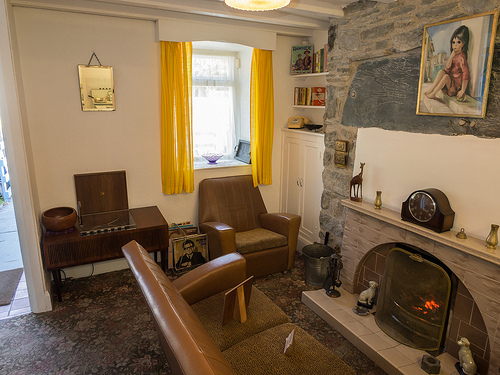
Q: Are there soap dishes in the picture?
A: No, there are no soap dishes.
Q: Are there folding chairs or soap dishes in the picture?
A: No, there are no soap dishes or folding chairs.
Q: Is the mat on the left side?
A: Yes, the mat is on the left of the image.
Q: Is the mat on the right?
A: No, the mat is on the left of the image.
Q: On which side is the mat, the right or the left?
A: The mat is on the left of the image.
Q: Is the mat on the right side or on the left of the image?
A: The mat is on the left of the image.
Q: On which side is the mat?
A: The mat is on the left of the image.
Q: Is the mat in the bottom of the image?
A: Yes, the mat is in the bottom of the image.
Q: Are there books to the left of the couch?
A: No, there is a mat to the left of the couch.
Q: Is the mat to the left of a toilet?
A: No, the mat is to the left of the couch.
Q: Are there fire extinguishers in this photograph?
A: No, there are no fire extinguishers.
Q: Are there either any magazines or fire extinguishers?
A: No, there are no fire extinguishers or magazines.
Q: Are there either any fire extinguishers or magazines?
A: No, there are no fire extinguishers or magazines.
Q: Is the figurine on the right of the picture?
A: Yes, the figurine is on the right of the image.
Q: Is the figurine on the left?
A: No, the figurine is on the right of the image.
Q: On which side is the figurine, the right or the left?
A: The figurine is on the right of the image.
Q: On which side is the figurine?
A: The figurine is on the right of the image.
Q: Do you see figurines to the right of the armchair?
A: Yes, there is a figurine to the right of the armchair.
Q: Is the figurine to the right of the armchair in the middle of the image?
A: Yes, the figurine is to the right of the armchair.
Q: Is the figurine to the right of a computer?
A: No, the figurine is to the right of the armchair.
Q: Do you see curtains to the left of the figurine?
A: Yes, there are curtains to the left of the figurine.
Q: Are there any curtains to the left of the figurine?
A: Yes, there are curtains to the left of the figurine.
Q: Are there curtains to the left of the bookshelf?
A: Yes, there are curtains to the left of the bookshelf.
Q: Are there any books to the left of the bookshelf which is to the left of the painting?
A: No, there are curtains to the left of the bookshelf.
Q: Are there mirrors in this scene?
A: Yes, there is a mirror.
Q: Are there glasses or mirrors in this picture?
A: Yes, there is a mirror.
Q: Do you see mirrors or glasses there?
A: Yes, there is a mirror.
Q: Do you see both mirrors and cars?
A: No, there is a mirror but no cars.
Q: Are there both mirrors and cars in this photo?
A: No, there is a mirror but no cars.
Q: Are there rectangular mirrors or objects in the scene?
A: Yes, there is a rectangular mirror.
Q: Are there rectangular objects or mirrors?
A: Yes, there is a rectangular mirror.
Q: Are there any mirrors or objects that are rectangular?
A: Yes, the mirror is rectangular.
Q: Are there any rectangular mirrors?
A: Yes, there is a rectangular mirror.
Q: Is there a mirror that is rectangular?
A: Yes, there is a mirror that is rectangular.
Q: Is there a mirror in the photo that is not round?
A: Yes, there is a rectangular mirror.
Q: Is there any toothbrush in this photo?
A: No, there are no toothbrushes.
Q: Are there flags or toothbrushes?
A: No, there are no toothbrushes or flags.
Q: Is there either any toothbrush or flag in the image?
A: No, there are no toothbrushes or flags.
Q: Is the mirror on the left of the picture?
A: Yes, the mirror is on the left of the image.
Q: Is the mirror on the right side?
A: No, the mirror is on the left of the image.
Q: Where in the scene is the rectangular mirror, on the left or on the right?
A: The mirror is on the left of the image.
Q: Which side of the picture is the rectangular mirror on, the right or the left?
A: The mirror is on the left of the image.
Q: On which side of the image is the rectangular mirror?
A: The mirror is on the left of the image.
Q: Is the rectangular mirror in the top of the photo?
A: Yes, the mirror is in the top of the image.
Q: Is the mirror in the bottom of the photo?
A: No, the mirror is in the top of the image.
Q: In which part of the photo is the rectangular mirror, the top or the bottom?
A: The mirror is in the top of the image.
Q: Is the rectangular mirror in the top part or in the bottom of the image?
A: The mirror is in the top of the image.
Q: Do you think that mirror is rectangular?
A: Yes, the mirror is rectangular.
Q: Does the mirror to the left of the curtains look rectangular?
A: Yes, the mirror is rectangular.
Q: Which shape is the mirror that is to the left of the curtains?
A: The mirror is rectangular.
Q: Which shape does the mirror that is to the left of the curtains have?
A: The mirror has rectangular shape.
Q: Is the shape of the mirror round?
A: No, the mirror is rectangular.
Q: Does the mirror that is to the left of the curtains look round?
A: No, the mirror is rectangular.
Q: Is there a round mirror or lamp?
A: No, there is a mirror but it is rectangular.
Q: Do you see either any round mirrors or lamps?
A: No, there is a mirror but it is rectangular.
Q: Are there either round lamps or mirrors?
A: No, there is a mirror but it is rectangular.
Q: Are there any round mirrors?
A: No, there is a mirror but it is rectangular.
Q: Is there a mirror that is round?
A: No, there is a mirror but it is rectangular.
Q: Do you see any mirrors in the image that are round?
A: No, there is a mirror but it is rectangular.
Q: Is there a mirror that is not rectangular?
A: No, there is a mirror but it is rectangular.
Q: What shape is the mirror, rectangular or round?
A: The mirror is rectangular.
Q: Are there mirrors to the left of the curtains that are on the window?
A: Yes, there is a mirror to the left of the curtains.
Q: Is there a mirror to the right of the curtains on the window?
A: No, the mirror is to the left of the curtains.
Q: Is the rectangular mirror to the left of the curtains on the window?
A: Yes, the mirror is to the left of the curtains.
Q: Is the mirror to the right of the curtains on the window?
A: No, the mirror is to the left of the curtains.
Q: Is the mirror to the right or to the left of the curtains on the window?
A: The mirror is to the left of the curtains.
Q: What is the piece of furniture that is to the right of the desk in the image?
A: The piece of furniture is an armchair.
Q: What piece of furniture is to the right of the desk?
A: The piece of furniture is an armchair.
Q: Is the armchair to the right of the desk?
A: Yes, the armchair is to the right of the desk.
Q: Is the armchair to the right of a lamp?
A: No, the armchair is to the right of the desk.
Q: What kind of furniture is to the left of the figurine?
A: The piece of furniture is an armchair.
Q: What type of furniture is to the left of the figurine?
A: The piece of furniture is an armchair.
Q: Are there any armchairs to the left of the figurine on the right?
A: Yes, there is an armchair to the left of the figurine.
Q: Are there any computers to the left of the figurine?
A: No, there is an armchair to the left of the figurine.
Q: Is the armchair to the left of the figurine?
A: Yes, the armchair is to the left of the figurine.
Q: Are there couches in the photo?
A: Yes, there is a couch.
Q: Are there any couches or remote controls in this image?
A: Yes, there is a couch.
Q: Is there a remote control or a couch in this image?
A: Yes, there is a couch.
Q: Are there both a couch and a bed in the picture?
A: No, there is a couch but no beds.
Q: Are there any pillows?
A: No, there are no pillows.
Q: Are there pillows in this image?
A: No, there are no pillows.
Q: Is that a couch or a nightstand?
A: That is a couch.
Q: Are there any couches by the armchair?
A: Yes, there is a couch by the armchair.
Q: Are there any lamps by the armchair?
A: No, there is a couch by the armchair.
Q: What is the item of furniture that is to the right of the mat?
A: The piece of furniture is a couch.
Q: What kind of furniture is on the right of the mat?
A: The piece of furniture is a couch.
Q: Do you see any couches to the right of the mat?
A: Yes, there is a couch to the right of the mat.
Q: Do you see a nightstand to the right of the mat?
A: No, there is a couch to the right of the mat.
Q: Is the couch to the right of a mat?
A: Yes, the couch is to the right of a mat.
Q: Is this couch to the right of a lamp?
A: No, the couch is to the right of a mat.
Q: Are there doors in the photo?
A: Yes, there is a door.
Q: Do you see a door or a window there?
A: Yes, there is a door.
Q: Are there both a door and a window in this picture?
A: Yes, there are both a door and a window.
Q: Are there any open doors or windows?
A: Yes, there is an open door.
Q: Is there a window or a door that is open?
A: Yes, the door is open.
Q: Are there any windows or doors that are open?
A: Yes, the door is open.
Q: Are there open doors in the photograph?
A: Yes, there is an open door.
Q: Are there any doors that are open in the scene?
A: Yes, there is an open door.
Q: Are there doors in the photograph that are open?
A: Yes, there is a door that is open.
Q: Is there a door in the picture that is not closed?
A: Yes, there is a open door.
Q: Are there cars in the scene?
A: No, there are no cars.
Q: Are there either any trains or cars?
A: No, there are no cars or trains.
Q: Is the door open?
A: Yes, the door is open.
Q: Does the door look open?
A: Yes, the door is open.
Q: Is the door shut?
A: No, the door is open.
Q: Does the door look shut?
A: No, the door is open.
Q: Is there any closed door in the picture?
A: No, there is a door but it is open.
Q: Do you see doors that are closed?
A: No, there is a door but it is open.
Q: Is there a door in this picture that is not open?
A: No, there is a door but it is open.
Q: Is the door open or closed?
A: The door is open.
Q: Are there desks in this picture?
A: Yes, there is a desk.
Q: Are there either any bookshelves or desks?
A: Yes, there is a desk.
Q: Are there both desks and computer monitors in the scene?
A: No, there is a desk but no computer monitors.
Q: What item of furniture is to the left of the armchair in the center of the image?
A: The piece of furniture is a desk.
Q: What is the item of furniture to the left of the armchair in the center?
A: The piece of furniture is a desk.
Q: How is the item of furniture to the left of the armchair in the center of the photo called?
A: The piece of furniture is a desk.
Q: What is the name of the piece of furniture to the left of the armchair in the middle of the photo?
A: The piece of furniture is a desk.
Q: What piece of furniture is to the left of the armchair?
A: The piece of furniture is a desk.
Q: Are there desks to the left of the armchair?
A: Yes, there is a desk to the left of the armchair.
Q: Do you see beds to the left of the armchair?
A: No, there is a desk to the left of the armchair.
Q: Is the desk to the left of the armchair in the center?
A: Yes, the desk is to the left of the armchair.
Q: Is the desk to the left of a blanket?
A: No, the desk is to the left of the armchair.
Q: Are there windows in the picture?
A: Yes, there is a window.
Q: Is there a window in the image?
A: Yes, there is a window.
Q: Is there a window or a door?
A: Yes, there is a window.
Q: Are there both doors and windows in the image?
A: Yes, there are both a window and a door.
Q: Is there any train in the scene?
A: No, there are no trains.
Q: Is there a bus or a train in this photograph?
A: No, there are no trains or buses.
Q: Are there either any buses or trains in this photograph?
A: No, there are no trains or buses.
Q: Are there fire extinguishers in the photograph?
A: No, there are no fire extinguishers.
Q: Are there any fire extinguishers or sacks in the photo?
A: No, there are no fire extinguishers or sacks.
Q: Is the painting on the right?
A: Yes, the painting is on the right of the image.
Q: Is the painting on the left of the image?
A: No, the painting is on the right of the image.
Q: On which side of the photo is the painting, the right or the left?
A: The painting is on the right of the image.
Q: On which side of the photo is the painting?
A: The painting is on the right of the image.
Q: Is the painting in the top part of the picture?
A: Yes, the painting is in the top of the image.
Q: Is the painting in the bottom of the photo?
A: No, the painting is in the top of the image.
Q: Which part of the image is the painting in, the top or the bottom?
A: The painting is in the top of the image.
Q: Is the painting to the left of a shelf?
A: No, the painting is to the right of a shelf.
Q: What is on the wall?
A: The painting is on the wall.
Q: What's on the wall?
A: The painting is on the wall.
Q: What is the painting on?
A: The painting is on the wall.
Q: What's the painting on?
A: The painting is on the wall.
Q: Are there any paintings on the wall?
A: Yes, there is a painting on the wall.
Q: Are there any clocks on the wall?
A: No, there is a painting on the wall.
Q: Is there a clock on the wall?
A: No, there is a painting on the wall.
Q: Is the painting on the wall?
A: Yes, the painting is on the wall.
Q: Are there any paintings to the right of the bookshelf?
A: Yes, there is a painting to the right of the bookshelf.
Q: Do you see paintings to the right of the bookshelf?
A: Yes, there is a painting to the right of the bookshelf.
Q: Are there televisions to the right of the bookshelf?
A: No, there is a painting to the right of the bookshelf.